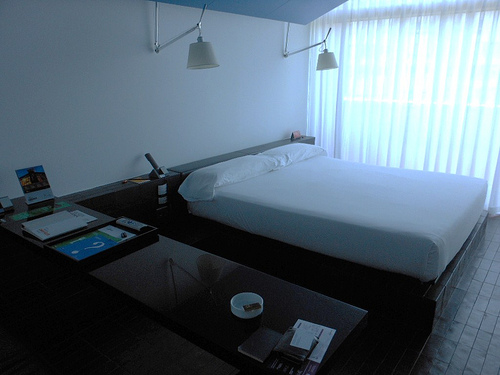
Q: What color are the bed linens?
A: White.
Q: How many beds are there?
A: 1.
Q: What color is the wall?
A: White.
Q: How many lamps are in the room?
A: 2.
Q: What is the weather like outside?
A: Sunny.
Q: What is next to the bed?
A: Oxygen tank.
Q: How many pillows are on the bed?
A: 2.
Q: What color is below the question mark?
A: Blue.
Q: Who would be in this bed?
A: A traveler.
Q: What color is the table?
A: Black.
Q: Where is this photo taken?
A: Hotel room.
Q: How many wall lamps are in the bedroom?
A: 2.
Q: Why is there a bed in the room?
A: Bedroom in a hotel.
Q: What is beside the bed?
A: Long desk.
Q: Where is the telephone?
A: Bed's headboard.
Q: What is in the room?
A: A bed.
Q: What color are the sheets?
A: White.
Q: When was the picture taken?
A: During the day.